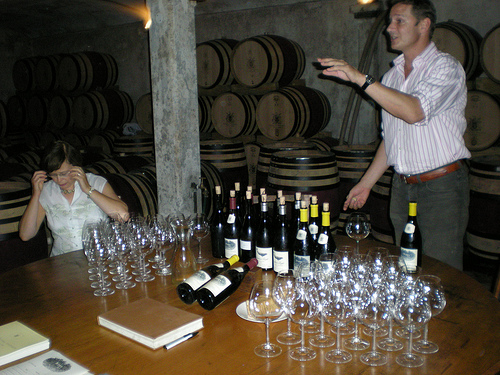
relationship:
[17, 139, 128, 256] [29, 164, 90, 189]
woman with hands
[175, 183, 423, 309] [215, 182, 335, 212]
bottle have cork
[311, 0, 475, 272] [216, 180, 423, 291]
guy standing near bottles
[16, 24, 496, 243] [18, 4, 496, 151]
barrels near wall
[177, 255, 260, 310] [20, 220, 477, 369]
wine bottle laying on table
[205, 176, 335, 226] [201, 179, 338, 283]
cork on top of bottle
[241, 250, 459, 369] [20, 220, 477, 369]
glasses on table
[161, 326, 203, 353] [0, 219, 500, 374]
pen on table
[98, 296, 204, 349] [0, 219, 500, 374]
book on table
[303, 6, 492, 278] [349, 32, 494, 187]
guy wearing shirt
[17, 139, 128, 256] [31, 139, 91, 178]
woman with hair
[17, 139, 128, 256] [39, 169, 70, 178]
woman with glasses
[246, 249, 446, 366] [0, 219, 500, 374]
wine glasses on table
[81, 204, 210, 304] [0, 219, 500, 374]
wine glasses on table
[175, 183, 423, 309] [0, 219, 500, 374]
bottle on table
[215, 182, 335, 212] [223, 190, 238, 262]
cork on bottle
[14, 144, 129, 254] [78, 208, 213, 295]
woman in front of glasses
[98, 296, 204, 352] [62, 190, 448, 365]
book on table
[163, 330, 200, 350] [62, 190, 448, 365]
pen on table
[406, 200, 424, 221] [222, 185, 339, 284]
yellow seal on bottle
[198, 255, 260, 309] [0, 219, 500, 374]
wine bottle on table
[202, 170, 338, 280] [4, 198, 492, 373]
wine on table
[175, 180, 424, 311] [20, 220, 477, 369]
wine on a table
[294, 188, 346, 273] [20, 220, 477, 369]
bottle on a table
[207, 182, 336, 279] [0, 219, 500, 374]
wine bottle on a table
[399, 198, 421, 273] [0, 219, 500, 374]
wine bottle on a table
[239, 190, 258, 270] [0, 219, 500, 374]
wine bottle on a table